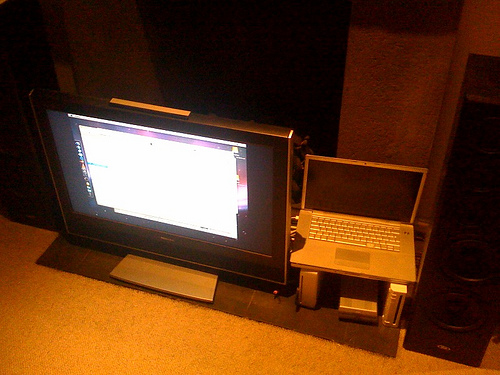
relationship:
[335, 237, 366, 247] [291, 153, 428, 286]
key on laptop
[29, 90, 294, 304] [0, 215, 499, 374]
television on top of floor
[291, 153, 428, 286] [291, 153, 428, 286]
laptop under laptop laptop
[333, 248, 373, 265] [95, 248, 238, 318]
mouse pad under laptop computer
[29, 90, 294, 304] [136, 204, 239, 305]
television with computer toolbar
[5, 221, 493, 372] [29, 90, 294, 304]
carpet in front of television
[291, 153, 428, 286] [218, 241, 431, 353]
laptop on a mount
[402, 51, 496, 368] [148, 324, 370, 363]
speaker on floor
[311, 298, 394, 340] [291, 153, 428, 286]
track pad of a laptop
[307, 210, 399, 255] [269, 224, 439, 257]
keyboard of a laptop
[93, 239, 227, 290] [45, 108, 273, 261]
bezel of a monitor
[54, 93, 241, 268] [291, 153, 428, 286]
screen of a laptop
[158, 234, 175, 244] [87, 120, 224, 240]
logo on lcd monitor